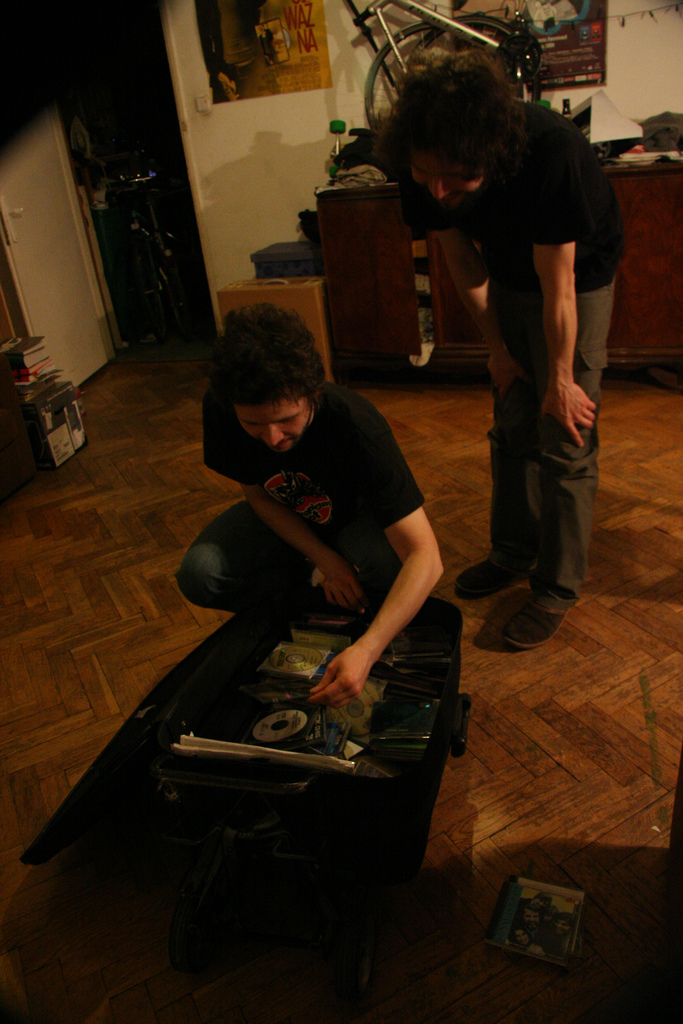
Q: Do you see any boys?
A: No, there are no boys.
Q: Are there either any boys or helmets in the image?
A: No, there are no boys or helmets.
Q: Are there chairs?
A: No, there are no chairs.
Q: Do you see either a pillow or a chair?
A: No, there are no chairs or pillows.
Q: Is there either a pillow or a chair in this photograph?
A: No, there are no chairs or pillows.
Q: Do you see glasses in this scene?
A: No, there are no glasses.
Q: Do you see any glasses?
A: No, there are no glasses.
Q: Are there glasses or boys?
A: No, there are no glasses or boys.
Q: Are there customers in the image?
A: No, there are no customers.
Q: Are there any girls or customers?
A: No, there are no customers or girls.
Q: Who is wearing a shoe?
A: The man is wearing a shoe.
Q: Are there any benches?
A: No, there are no benches.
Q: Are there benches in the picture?
A: No, there are no benches.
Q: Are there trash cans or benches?
A: No, there are no benches or trash cans.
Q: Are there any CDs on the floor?
A: Yes, there is a CD on the floor.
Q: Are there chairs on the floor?
A: No, there is a CD on the floor.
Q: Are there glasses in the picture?
A: No, there are no glasses.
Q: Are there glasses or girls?
A: No, there are no glasses or girls.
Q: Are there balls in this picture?
A: No, there are no balls.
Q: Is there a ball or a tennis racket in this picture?
A: No, there are no balls or rackets.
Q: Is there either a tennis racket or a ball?
A: No, there are no balls or rackets.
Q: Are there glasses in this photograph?
A: No, there are no glasses.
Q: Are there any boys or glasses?
A: No, there are no glasses or boys.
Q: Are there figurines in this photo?
A: No, there are no figurines.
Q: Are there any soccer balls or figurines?
A: No, there are no figurines or soccer balls.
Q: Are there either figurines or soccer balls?
A: No, there are no figurines or soccer balls.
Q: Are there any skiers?
A: No, there are no skiers.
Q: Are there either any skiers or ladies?
A: No, there are no skiers or ladies.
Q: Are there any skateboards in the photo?
A: No, there are no skateboards.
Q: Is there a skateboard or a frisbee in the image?
A: No, there are no skateboards or frisbees.